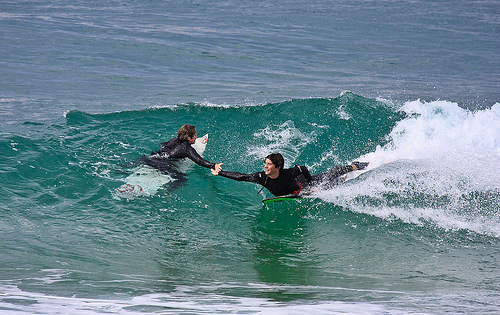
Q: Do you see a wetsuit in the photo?
A: Yes, there is a wetsuit.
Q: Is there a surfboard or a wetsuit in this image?
A: Yes, there is a wetsuit.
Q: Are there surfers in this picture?
A: Yes, there is a surfer.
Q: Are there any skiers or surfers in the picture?
A: Yes, there is a surfer.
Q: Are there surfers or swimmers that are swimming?
A: Yes, the surfer is swimming.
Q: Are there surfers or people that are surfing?
A: Yes, the surfer is surfing.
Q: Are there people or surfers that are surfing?
A: Yes, the surfer is surfing.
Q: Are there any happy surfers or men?
A: Yes, there is a happy surfer.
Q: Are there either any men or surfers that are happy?
A: Yes, the surfer is happy.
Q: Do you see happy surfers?
A: Yes, there is a happy surfer.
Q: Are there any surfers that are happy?
A: Yes, there is a surfer that is happy.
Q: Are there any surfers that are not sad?
A: Yes, there is a happy surfer.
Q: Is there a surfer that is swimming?
A: Yes, there is a surfer that is swimming.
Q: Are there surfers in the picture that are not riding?
A: Yes, there is a surfer that is swimming.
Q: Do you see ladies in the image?
A: No, there are no ladies.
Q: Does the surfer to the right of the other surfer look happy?
A: Yes, the surfer is happy.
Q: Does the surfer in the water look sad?
A: No, the surfer is happy.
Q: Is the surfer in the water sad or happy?
A: The surfer is happy.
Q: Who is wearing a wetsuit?
A: The surfer is wearing a wetsuit.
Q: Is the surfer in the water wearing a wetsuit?
A: Yes, the surfer is wearing a wetsuit.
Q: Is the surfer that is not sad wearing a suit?
A: No, the surfer is wearing a wetsuit.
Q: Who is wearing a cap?
A: The surfer is wearing a cap.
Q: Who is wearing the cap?
A: The surfer is wearing a cap.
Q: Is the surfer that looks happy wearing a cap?
A: Yes, the surfer is wearing a cap.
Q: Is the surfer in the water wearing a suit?
A: No, the surfer is wearing a cap.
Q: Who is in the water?
A: The surfer is in the water.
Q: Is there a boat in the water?
A: No, there is a surfer in the water.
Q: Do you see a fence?
A: No, there are no fences.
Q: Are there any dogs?
A: No, there are no dogs.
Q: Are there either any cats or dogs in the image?
A: No, there are no dogs or cats.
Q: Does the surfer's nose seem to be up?
A: Yes, the nose is up.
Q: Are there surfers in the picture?
A: Yes, there is a surfer.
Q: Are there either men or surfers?
A: Yes, there is a surfer.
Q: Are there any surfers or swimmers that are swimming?
A: Yes, the surfer is swimming.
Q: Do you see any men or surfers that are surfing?
A: Yes, the surfer is surfing.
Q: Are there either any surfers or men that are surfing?
A: Yes, the surfer is surfing.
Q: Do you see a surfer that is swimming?
A: Yes, there is a surfer that is swimming.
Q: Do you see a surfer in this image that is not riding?
A: Yes, there is a surfer that is swimming .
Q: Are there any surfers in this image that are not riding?
A: Yes, there is a surfer that is swimming.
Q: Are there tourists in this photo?
A: No, there are no tourists.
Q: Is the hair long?
A: Yes, the hair is long.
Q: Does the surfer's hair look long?
A: Yes, the hair is long.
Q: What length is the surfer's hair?
A: The hair is long.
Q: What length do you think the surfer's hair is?
A: The hair is long.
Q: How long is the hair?
A: The hair is long.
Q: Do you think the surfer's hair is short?
A: No, the hair is long.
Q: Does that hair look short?
A: No, the hair is long.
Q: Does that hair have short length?
A: No, the hair is long.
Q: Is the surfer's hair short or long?
A: The hair is long.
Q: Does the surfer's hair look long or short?
A: The hair is long.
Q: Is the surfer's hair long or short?
A: The hair is long.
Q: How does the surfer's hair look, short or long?
A: The hair is long.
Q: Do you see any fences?
A: No, there are no fences.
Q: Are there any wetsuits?
A: Yes, there is a wetsuit.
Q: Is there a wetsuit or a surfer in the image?
A: Yes, there is a wetsuit.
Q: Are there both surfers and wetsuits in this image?
A: Yes, there are both a wetsuit and a surfer.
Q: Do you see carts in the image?
A: No, there are no carts.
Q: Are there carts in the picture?
A: No, there are no carts.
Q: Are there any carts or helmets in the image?
A: No, there are no carts or helmets.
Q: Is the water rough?
A: Yes, the water is rough.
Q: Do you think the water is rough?
A: Yes, the water is rough.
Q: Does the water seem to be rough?
A: Yes, the water is rough.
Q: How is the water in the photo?
A: The water is rough.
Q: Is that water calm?
A: No, the water is rough.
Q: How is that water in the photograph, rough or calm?
A: The water is rough.